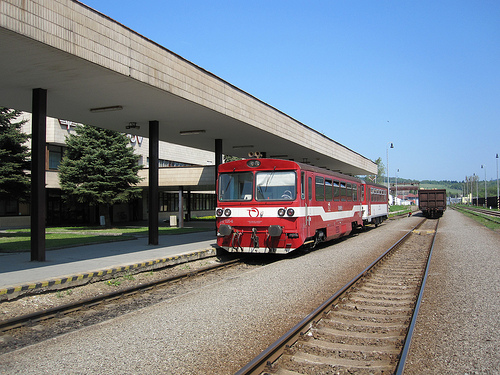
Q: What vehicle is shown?
A: Train.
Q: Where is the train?
A: On the train tracks.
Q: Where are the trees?
A: Behind the bridge.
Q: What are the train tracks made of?
A: Wood and metal.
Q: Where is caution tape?
A: On the curb.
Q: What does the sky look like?
A: Clear.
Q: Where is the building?
A: Left of red train.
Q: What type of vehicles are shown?
A: Trains.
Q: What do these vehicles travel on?
A: Tracks.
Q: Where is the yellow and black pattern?
A: Edge of platform.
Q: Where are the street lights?
A: Lining the tracks.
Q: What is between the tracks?
A: Gravel.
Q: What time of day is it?
A: Daytime.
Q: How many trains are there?
A: Two.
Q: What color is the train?
A: Red.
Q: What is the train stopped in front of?
A: A building.